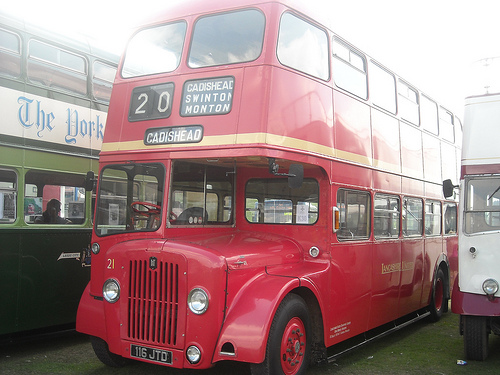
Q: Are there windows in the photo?
A: Yes, there is a window.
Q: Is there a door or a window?
A: Yes, there is a window.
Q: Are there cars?
A: No, there are no cars.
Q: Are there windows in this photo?
A: Yes, there is a window.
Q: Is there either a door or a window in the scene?
A: Yes, there is a window.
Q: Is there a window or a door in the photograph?
A: Yes, there is a window.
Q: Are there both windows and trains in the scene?
A: No, there is a window but no trains.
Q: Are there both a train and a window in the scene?
A: No, there is a window but no trains.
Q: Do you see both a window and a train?
A: No, there is a window but no trains.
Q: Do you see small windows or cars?
A: Yes, there is a small window.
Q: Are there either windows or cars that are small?
A: Yes, the window is small.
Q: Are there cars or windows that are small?
A: Yes, the window is small.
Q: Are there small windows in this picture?
A: Yes, there is a small window.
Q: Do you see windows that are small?
A: Yes, there is a small window.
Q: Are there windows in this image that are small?
A: Yes, there is a window that is small.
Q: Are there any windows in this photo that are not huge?
A: Yes, there is a small window.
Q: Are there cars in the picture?
A: No, there are no cars.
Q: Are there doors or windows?
A: Yes, there is a window.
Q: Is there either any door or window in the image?
A: Yes, there is a window.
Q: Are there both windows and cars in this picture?
A: No, there is a window but no cars.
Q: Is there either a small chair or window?
A: Yes, there is a small window.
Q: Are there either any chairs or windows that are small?
A: Yes, the window is small.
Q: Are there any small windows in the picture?
A: Yes, there is a small window.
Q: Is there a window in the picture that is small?
A: Yes, there is a window that is small.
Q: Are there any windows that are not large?
A: Yes, there is a small window.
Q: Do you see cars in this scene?
A: No, there are no cars.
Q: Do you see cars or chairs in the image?
A: No, there are no cars or chairs.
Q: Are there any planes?
A: No, there are no planes.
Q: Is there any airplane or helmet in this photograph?
A: No, there are no airplanes or helmets.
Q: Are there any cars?
A: No, there are no cars.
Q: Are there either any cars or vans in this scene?
A: No, there are no cars or vans.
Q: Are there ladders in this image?
A: No, there are no ladders.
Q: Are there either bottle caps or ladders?
A: No, there are no ladders or bottle caps.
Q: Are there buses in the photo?
A: Yes, there is a bus.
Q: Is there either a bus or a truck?
A: Yes, there is a bus.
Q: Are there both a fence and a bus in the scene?
A: No, there is a bus but no fences.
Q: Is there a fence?
A: No, there are no fences.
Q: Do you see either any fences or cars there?
A: No, there are no fences or cars.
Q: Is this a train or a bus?
A: This is a bus.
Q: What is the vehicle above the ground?
A: The vehicle is a bus.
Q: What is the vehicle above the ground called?
A: The vehicle is a bus.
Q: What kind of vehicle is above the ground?
A: The vehicle is a bus.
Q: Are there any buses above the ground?
A: Yes, there is a bus above the ground.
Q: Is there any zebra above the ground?
A: No, there is a bus above the ground.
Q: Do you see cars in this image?
A: No, there are no cars.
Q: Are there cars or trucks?
A: No, there are no cars or trucks.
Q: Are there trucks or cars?
A: No, there are no cars or trucks.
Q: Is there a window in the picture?
A: Yes, there is a window.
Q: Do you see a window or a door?
A: Yes, there is a window.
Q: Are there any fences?
A: No, there are no fences.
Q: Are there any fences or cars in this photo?
A: No, there are no fences or cars.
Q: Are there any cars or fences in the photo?
A: No, there are no fences or cars.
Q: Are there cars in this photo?
A: No, there are no cars.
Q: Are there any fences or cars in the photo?
A: No, there are no cars or fences.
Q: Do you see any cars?
A: No, there are no cars.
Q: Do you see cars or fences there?
A: No, there are no cars or fences.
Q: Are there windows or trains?
A: Yes, there is a window.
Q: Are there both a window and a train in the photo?
A: No, there is a window but no trains.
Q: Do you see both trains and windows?
A: No, there is a window but no trains.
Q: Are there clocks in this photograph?
A: No, there are no clocks.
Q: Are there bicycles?
A: No, there are no bicycles.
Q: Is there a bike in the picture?
A: No, there are no bikes.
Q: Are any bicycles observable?
A: No, there are no bicycles.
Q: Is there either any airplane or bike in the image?
A: No, there are no bikes or airplanes.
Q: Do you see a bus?
A: Yes, there is a bus.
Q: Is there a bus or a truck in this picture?
A: Yes, there is a bus.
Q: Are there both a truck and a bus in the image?
A: No, there is a bus but no trucks.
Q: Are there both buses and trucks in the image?
A: No, there is a bus but no trucks.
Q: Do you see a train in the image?
A: No, there are no trains.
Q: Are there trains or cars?
A: No, there are no trains or cars.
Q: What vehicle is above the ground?
A: The vehicle is a bus.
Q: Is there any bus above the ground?
A: Yes, there is a bus above the ground.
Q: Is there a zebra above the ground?
A: No, there is a bus above the ground.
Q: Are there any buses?
A: Yes, there is a bus.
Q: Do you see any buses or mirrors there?
A: Yes, there is a bus.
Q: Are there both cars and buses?
A: No, there is a bus but no cars.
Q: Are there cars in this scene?
A: No, there are no cars.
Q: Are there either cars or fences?
A: No, there are no cars or fences.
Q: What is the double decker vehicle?
A: The vehicle is a bus.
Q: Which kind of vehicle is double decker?
A: The vehicle is a bus.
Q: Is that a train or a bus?
A: That is a bus.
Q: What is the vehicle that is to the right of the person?
A: The vehicle is a bus.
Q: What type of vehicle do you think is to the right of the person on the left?
A: The vehicle is a bus.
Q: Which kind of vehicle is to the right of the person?
A: The vehicle is a bus.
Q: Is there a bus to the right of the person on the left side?
A: Yes, there is a bus to the right of the person.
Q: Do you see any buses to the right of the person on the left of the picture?
A: Yes, there is a bus to the right of the person.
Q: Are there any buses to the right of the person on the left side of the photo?
A: Yes, there is a bus to the right of the person.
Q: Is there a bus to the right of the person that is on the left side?
A: Yes, there is a bus to the right of the person.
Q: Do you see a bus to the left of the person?
A: No, the bus is to the right of the person.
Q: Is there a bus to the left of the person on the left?
A: No, the bus is to the right of the person.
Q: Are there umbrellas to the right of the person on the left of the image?
A: No, there is a bus to the right of the person.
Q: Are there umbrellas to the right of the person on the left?
A: No, there is a bus to the right of the person.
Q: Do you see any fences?
A: No, there are no fences.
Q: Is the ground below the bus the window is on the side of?
A: Yes, the ground is below the bus.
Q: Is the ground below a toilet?
A: No, the ground is below the bus.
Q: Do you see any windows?
A: Yes, there is a window.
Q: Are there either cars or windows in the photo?
A: Yes, there is a window.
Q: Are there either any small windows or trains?
A: Yes, there is a small window.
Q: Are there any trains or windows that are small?
A: Yes, the window is small.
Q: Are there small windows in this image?
A: Yes, there is a small window.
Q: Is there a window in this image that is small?
A: Yes, there is a window that is small.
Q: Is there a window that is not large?
A: Yes, there is a small window.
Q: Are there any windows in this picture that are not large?
A: Yes, there is a small window.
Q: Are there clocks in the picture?
A: No, there are no clocks.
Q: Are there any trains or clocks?
A: No, there are no clocks or trains.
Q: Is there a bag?
A: No, there are no bags.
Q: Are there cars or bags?
A: No, there are no bags or cars.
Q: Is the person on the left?
A: Yes, the person is on the left of the image.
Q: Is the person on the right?
A: No, the person is on the left of the image.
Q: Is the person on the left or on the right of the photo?
A: The person is on the left of the image.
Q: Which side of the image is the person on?
A: The person is on the left of the image.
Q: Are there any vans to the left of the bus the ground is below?
A: No, there is a person to the left of the bus.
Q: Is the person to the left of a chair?
A: No, the person is to the left of the bus.